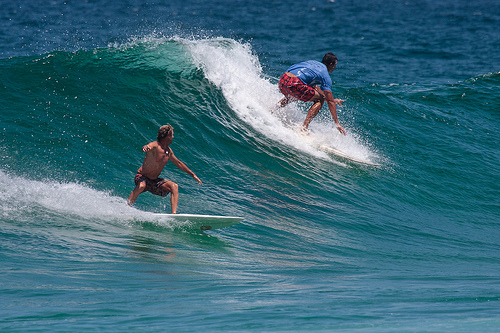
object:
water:
[0, 0, 500, 330]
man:
[128, 122, 202, 213]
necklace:
[160, 143, 169, 154]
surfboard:
[154, 214, 244, 230]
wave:
[0, 36, 499, 93]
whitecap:
[189, 36, 381, 170]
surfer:
[259, 105, 377, 167]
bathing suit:
[277, 61, 333, 101]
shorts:
[135, 174, 172, 197]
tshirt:
[284, 59, 332, 91]